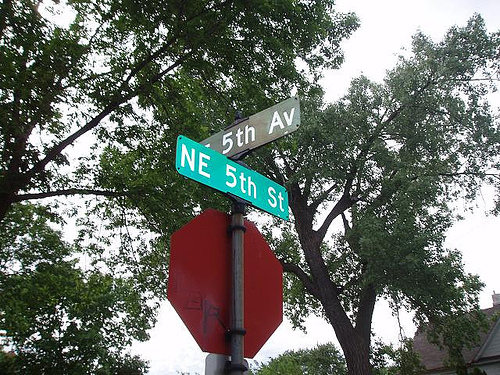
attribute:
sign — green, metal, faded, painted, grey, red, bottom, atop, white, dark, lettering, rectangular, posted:
[168, 84, 275, 203]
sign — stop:
[166, 227, 272, 335]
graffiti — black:
[179, 298, 250, 356]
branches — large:
[64, 38, 233, 185]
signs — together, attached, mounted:
[220, 208, 296, 356]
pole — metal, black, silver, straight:
[224, 232, 273, 361]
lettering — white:
[187, 148, 302, 212]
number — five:
[219, 165, 244, 188]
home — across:
[384, 287, 480, 370]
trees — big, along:
[104, 50, 262, 148]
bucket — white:
[482, 289, 500, 303]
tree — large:
[20, 44, 165, 363]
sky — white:
[148, 325, 192, 373]